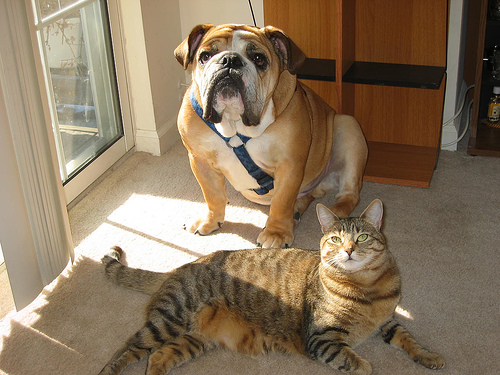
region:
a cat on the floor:
[98, 208, 438, 370]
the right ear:
[315, 205, 336, 230]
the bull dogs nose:
[217, 52, 246, 68]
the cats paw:
[418, 351, 449, 368]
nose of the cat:
[345, 244, 356, 254]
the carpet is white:
[417, 228, 467, 282]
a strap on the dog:
[245, 157, 267, 180]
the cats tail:
[103, 252, 128, 281]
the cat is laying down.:
[87, 202, 439, 372]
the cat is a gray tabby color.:
[80, 205, 443, 372]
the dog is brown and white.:
[170, 19, 368, 243]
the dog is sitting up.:
[171, 22, 368, 245]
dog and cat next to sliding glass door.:
[93, 17, 430, 367]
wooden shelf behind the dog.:
[258, 2, 450, 193]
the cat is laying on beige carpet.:
[82, 200, 431, 374]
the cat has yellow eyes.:
[328, 231, 371, 246]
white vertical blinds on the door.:
[1, 0, 80, 310]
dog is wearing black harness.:
[188, 84, 276, 194]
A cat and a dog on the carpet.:
[182, 161, 184, 179]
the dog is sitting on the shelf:
[331, 147, 388, 202]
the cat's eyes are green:
[355, 232, 370, 245]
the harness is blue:
[230, 149, 261, 169]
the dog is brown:
[293, 111, 321, 138]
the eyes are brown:
[249, 53, 266, 71]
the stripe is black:
[312, 323, 334, 338]